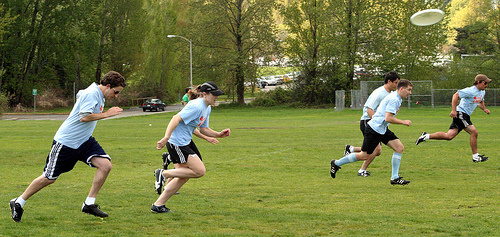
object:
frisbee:
[408, 9, 446, 27]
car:
[140, 98, 168, 113]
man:
[414, 74, 491, 164]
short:
[165, 139, 202, 164]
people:
[9, 72, 491, 223]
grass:
[254, 134, 306, 173]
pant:
[161, 139, 207, 193]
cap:
[194, 82, 226, 95]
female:
[150, 82, 230, 215]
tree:
[0, 0, 67, 108]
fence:
[359, 77, 500, 108]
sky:
[273, 2, 314, 45]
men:
[342, 71, 402, 177]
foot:
[152, 169, 169, 196]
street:
[100, 102, 185, 121]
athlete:
[327, 78, 412, 186]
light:
[166, 34, 195, 88]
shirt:
[167, 98, 212, 146]